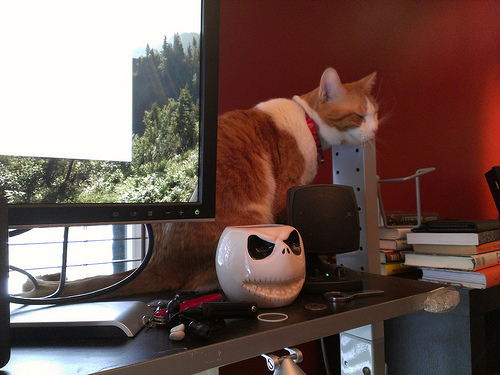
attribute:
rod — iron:
[330, 131, 383, 370]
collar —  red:
[303, 111, 329, 166]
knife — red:
[149, 289, 221, 336]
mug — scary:
[212, 217, 304, 307]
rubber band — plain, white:
[255, 308, 285, 325]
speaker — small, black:
[282, 177, 365, 290]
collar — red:
[291, 99, 326, 158]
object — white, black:
[215, 222, 307, 311]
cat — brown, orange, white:
[18, 66, 385, 297]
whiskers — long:
[373, 107, 393, 126]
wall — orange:
[218, 3, 498, 214]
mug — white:
[213, 218, 309, 311]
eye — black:
[282, 226, 302, 256]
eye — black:
[245, 233, 276, 260]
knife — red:
[136, 284, 224, 329]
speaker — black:
[285, 182, 364, 300]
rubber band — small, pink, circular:
[255, 307, 286, 324]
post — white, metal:
[330, 136, 383, 278]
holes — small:
[332, 144, 370, 272]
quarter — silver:
[304, 300, 327, 315]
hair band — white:
[256, 307, 287, 322]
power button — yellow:
[192, 209, 202, 218]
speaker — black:
[290, 189, 362, 255]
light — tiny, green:
[345, 206, 349, 216]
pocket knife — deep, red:
[143, 291, 224, 324]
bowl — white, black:
[213, 219, 305, 313]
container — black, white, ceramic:
[211, 220, 311, 305]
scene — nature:
[128, 45, 190, 188]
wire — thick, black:
[6, 234, 156, 300]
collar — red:
[303, 109, 319, 140]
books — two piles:
[410, 219, 496, 288]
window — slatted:
[10, 230, 150, 281]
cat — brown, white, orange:
[209, 62, 387, 222]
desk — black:
[0, 258, 464, 373]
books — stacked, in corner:
[370, 180, 498, 313]